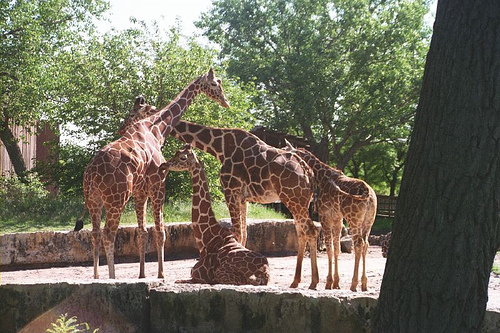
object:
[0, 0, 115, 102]
branch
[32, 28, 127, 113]
branch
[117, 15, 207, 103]
branch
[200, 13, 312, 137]
branch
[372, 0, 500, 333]
tree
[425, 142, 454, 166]
bark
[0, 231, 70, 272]
wall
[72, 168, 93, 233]
tail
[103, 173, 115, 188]
spot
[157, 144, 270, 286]
giraffe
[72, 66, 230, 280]
giraffe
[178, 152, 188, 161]
eye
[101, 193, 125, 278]
legs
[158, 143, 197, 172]
head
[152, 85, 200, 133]
neck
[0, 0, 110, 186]
tree